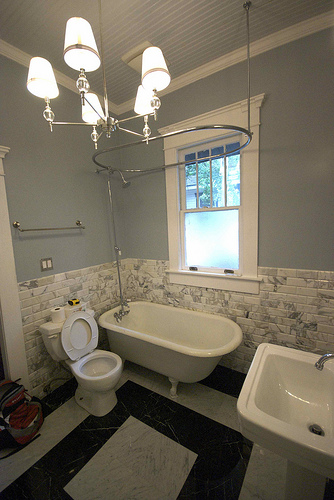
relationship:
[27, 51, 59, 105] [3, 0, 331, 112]
light hangs from ceiling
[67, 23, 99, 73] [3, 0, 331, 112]
light hangs from ceiling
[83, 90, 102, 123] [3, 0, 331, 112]
light hangs from ceiling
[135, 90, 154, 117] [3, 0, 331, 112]
light hangs from ceiling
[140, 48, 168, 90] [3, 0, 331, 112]
light hangs from ceiling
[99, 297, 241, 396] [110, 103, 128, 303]
bathtub in corner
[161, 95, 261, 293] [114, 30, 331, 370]
window on wall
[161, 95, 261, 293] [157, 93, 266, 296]
window has frame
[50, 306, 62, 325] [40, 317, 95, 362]
tissue on tank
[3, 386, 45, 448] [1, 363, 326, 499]
backpack on floor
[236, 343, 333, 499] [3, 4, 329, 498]
sink in bathroom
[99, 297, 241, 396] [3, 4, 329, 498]
bathtub in bathroom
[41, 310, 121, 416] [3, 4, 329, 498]
toilet in bathroom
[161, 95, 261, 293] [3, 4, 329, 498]
window in bathroom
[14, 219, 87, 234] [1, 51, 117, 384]
towel rack on wall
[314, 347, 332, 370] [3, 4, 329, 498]
faucet in bathroom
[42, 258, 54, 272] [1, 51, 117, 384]
light switch on wall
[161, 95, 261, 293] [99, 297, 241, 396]
window over bathtub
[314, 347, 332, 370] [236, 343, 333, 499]
faucet on sink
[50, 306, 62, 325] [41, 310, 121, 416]
tissue on toilet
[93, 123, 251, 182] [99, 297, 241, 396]
curtain holder for bathtub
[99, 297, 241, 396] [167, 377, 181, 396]
bathtub has claw foot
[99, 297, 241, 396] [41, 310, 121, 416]
bathtub next to toilet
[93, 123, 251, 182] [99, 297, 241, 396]
curtain holder above bathtub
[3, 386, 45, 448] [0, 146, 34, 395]
backpack by door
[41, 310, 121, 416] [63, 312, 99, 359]
toilet has toilet seat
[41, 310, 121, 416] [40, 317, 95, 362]
toilet has tank